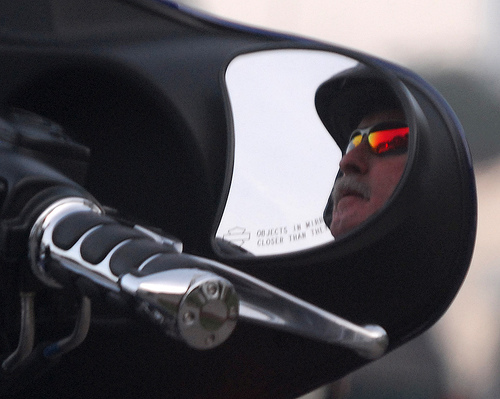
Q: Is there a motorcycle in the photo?
A: Yes, there is a motorcycle.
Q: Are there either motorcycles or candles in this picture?
A: Yes, there is a motorcycle.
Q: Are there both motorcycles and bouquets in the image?
A: No, there is a motorcycle but no bouquets.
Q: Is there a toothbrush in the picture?
A: No, there are no toothbrushes.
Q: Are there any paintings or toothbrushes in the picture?
A: No, there are no toothbrushes or paintings.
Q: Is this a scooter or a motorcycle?
A: This is a motorcycle.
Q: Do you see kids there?
A: No, there are no kids.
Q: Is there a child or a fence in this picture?
A: No, there are no children or fences.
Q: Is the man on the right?
A: Yes, the man is on the right of the image.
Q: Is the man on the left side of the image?
A: No, the man is on the right of the image.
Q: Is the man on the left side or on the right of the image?
A: The man is on the right of the image.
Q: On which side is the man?
A: The man is on the right of the image.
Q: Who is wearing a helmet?
A: The man is wearing a helmet.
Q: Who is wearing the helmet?
A: The man is wearing a helmet.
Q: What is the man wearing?
A: The man is wearing a helmet.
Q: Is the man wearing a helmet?
A: Yes, the man is wearing a helmet.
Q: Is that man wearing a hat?
A: No, the man is wearing a helmet.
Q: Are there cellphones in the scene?
A: No, there are no cellphones.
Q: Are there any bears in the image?
A: No, there are no bears.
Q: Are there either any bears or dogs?
A: No, there are no bears or dogs.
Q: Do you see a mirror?
A: Yes, there is a mirror.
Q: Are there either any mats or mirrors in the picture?
A: Yes, there is a mirror.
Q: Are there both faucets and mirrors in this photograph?
A: No, there is a mirror but no faucets.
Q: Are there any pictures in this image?
A: No, there are no pictures.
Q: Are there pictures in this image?
A: No, there are no pictures.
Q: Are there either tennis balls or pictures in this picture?
A: No, there are no pictures or tennis balls.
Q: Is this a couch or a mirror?
A: This is a mirror.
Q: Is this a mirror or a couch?
A: This is a mirror.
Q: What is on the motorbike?
A: The mirror is on the motorbike.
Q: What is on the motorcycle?
A: The mirror is on the motorbike.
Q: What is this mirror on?
A: The mirror is on the motorbike.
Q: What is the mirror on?
A: The mirror is on the motorbike.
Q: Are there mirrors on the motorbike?
A: Yes, there is a mirror on the motorbike.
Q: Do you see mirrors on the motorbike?
A: Yes, there is a mirror on the motorbike.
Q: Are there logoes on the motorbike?
A: No, there is a mirror on the motorbike.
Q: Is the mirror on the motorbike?
A: Yes, the mirror is on the motorbike.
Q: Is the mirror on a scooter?
A: No, the mirror is on the motorbike.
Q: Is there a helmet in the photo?
A: Yes, there is a helmet.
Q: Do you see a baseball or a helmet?
A: Yes, there is a helmet.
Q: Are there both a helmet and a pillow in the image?
A: No, there is a helmet but no pillows.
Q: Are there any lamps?
A: No, there are no lamps.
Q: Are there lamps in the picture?
A: No, there are no lamps.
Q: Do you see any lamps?
A: No, there are no lamps.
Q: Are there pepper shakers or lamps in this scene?
A: No, there are no lamps or pepper shakers.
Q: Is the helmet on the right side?
A: Yes, the helmet is on the right of the image.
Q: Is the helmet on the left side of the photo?
A: No, the helmet is on the right of the image.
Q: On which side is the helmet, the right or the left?
A: The helmet is on the right of the image.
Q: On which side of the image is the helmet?
A: The helmet is on the right of the image.